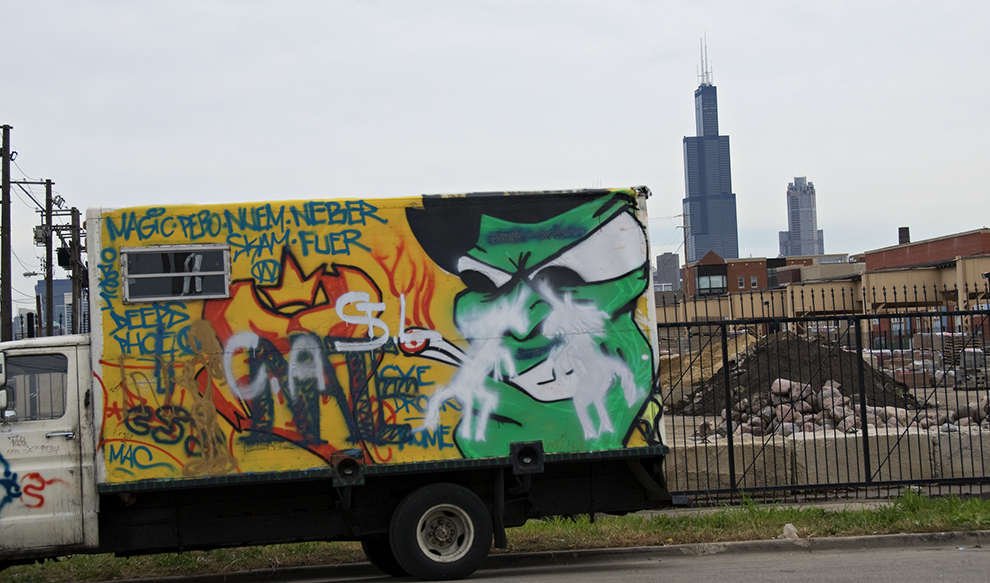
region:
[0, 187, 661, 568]
green face painted on a truck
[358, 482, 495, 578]
back wheels on a truck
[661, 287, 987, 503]
a black steel gate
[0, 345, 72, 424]
driver's window of a truck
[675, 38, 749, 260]
a tall skyscraper building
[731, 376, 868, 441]
a pile of stones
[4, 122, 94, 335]
a row of powerline poles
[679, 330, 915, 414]
a mound of dirt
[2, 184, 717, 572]
a yellow and white truck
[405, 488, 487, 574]
Small black tire with white rim.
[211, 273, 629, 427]
White spray paint on the side of the van.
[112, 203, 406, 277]
Blue painted letters on the side of truck.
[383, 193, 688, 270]
Large green ghost with black hair.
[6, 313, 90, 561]
Front of truck with orange and blue writing on it.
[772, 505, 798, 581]
Small piece of trash on the ground.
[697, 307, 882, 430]
Mound of rocks in the dirt.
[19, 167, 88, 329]
Group of long brown poles on the side.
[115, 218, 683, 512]
yellow and green sign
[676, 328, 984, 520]
black fence near trailer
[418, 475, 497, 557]
black tire on trailer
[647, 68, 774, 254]
grey tower in distance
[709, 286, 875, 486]
fence is black iron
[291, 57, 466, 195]
grey and white sky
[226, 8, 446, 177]
white clouds in sky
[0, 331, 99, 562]
white front of truck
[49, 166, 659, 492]
graffiti etchings on the back of a truck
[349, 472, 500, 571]
medium sized circular car tire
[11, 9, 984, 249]
clear overcast sky with no clouds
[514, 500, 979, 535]
green grass growing side of street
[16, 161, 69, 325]
black telephone pole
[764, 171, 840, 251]
medium sized skyscraper in background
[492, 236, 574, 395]
the face is green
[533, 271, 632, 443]
the unicorn is white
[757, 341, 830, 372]
the dirt is in a pile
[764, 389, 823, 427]
the rocks are in a pile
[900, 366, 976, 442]
the fence is black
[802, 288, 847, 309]
the building is tan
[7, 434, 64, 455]
the truck is white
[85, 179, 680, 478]
grafitti on side of truck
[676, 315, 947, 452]
pile of dirt behind fence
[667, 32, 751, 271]
large building in distance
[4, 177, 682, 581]
truck parked by sidewalk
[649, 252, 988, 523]
large gate by sidewalk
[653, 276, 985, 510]
gate by sidewalk is large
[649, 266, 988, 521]
large gate is black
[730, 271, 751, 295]
window on side of brick building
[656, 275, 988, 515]
metal black fence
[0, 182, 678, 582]
white truck with graffiti on back of it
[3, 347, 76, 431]
window on front of truck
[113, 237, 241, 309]
window on back of truck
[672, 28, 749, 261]
tall building behind brick building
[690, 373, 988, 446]
pile of grey rocks behind black metal fence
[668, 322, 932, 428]
pile of black dirt behind pile of rocks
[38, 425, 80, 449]
silver handle on truck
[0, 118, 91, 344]
electric line poles behind truck